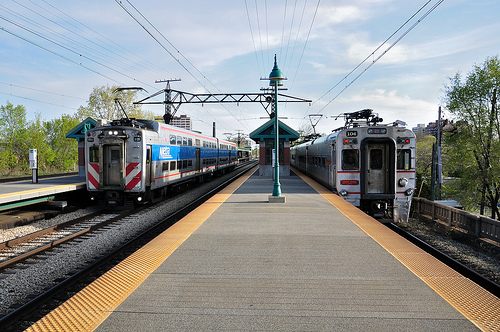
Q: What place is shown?
A: It is a station.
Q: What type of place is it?
A: It is a station.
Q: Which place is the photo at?
A: It is at the station.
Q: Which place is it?
A: It is a station.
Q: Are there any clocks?
A: No, there are no clocks.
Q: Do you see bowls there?
A: No, there are no bowls.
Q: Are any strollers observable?
A: No, there are no strollers.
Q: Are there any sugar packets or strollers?
A: No, there are no strollers or sugar packets.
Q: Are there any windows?
A: Yes, there are windows.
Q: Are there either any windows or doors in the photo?
A: Yes, there are windows.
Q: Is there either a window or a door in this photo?
A: Yes, there are windows.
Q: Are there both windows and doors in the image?
A: Yes, there are both windows and doors.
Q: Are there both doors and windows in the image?
A: Yes, there are both windows and doors.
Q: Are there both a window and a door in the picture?
A: Yes, there are both a window and a door.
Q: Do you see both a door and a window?
A: Yes, there are both a window and a door.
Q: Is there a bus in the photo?
A: No, there are no buses.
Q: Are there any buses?
A: No, there are no buses.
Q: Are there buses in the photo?
A: No, there are no buses.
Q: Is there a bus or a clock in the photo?
A: No, there are no buses or clocks.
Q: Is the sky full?
A: Yes, the sky is full.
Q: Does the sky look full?
A: Yes, the sky is full.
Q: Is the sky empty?
A: No, the sky is full.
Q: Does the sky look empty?
A: No, the sky is full.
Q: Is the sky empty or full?
A: The sky is full.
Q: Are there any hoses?
A: No, there are no hoses.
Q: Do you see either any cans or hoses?
A: No, there are no hoses or cans.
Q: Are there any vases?
A: No, there are no vases.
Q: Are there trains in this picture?
A: Yes, there is a train.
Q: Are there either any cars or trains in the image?
A: Yes, there is a train.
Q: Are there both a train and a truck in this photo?
A: No, there is a train but no trucks.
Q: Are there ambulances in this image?
A: No, there are no ambulances.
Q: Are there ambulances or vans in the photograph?
A: No, there are no ambulances or vans.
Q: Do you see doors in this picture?
A: Yes, there is a door.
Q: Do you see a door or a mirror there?
A: Yes, there is a door.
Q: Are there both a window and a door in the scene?
A: Yes, there are both a door and a window.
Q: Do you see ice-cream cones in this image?
A: No, there are no ice-cream cones.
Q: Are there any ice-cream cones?
A: No, there are no ice-cream cones.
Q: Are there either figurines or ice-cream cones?
A: No, there are no ice-cream cones or figurines.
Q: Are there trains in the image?
A: Yes, there are trains.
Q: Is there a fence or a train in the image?
A: Yes, there are trains.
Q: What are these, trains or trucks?
A: These are trains.